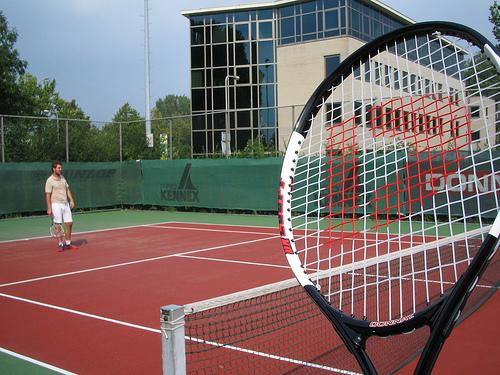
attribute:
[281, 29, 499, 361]
tennis racket — black, white, red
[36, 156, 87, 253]
man — waiting, playing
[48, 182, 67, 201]
shirt — green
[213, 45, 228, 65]
window — glass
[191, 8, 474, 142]
building — glass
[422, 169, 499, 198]
lettering — red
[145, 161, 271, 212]
fence — green, big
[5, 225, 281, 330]
court — red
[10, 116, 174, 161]
fence — metal